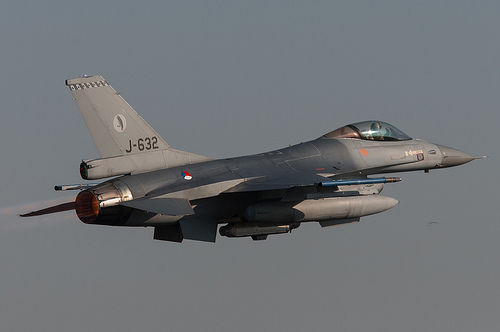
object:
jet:
[18, 74, 490, 244]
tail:
[66, 74, 214, 180]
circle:
[112, 113, 126, 133]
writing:
[125, 136, 159, 154]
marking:
[182, 171, 192, 181]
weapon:
[318, 177, 402, 188]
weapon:
[219, 222, 301, 241]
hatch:
[350, 120, 413, 142]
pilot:
[364, 122, 385, 140]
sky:
[2, 0, 499, 332]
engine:
[73, 178, 134, 228]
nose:
[433, 143, 489, 169]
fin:
[180, 214, 218, 243]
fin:
[153, 224, 185, 243]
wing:
[220, 170, 403, 193]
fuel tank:
[245, 194, 400, 228]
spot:
[359, 148, 367, 157]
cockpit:
[320, 119, 414, 142]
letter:
[125, 140, 132, 153]